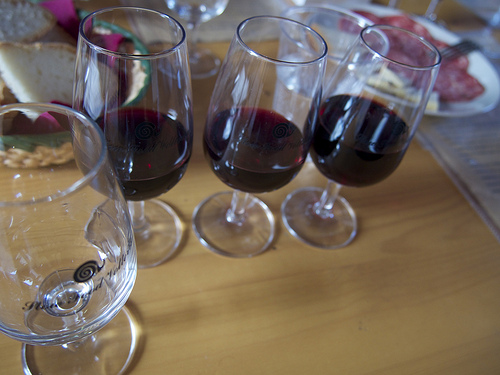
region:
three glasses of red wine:
[80, 15, 442, 263]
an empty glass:
[2, 105, 138, 370]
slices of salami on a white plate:
[392, 15, 472, 96]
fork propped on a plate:
[442, 28, 497, 73]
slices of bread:
[5, 6, 75, 102]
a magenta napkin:
[50, 1, 80, 23]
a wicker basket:
[0, 136, 76, 167]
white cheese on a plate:
[365, 61, 440, 109]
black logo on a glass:
[60, 245, 111, 295]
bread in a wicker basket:
[3, 7, 123, 167]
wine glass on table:
[80, 24, 202, 267]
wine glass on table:
[223, 25, 310, 265]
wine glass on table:
[305, 25, 427, 251]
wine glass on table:
[2, 170, 152, 373]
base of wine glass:
[283, 198, 368, 238]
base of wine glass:
[205, 198, 266, 254]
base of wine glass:
[122, 208, 176, 258]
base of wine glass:
[30, 335, 141, 365]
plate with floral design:
[376, 28, 483, 116]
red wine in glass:
[210, 135, 287, 192]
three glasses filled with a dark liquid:
[72, 11, 437, 264]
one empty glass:
[8, 94, 179, 374]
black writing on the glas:
[19, 242, 135, 318]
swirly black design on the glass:
[64, 251, 110, 282]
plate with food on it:
[340, 5, 499, 134]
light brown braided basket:
[4, 5, 179, 182]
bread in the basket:
[1, 26, 123, 134]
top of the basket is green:
[101, 17, 172, 107]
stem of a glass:
[171, 27, 219, 83]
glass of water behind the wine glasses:
[273, 9, 383, 173]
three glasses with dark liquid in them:
[78, 7, 447, 287]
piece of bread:
[4, 36, 103, 116]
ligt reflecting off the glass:
[372, 109, 390, 159]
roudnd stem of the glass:
[289, 180, 365, 253]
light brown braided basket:
[4, 140, 87, 175]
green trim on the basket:
[107, 17, 161, 70]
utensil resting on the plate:
[437, 21, 483, 71]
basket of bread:
[1, 0, 165, 190]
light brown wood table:
[230, 275, 385, 347]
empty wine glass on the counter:
[0, 92, 151, 372]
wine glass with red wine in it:
[301, 27, 463, 264]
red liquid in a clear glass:
[205, 99, 312, 194]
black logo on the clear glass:
[57, 236, 114, 310]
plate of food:
[310, 2, 498, 124]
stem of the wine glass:
[196, 175, 294, 273]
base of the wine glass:
[274, 171, 391, 262]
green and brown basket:
[4, 131, 112, 184]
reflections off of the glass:
[89, 55, 207, 109]